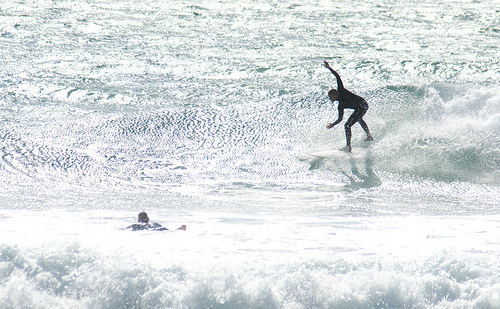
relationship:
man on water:
[312, 61, 374, 154] [1, 2, 490, 210]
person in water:
[126, 206, 188, 233] [1, 2, 490, 210]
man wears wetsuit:
[312, 61, 374, 154] [342, 87, 368, 137]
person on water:
[126, 206, 188, 233] [1, 2, 490, 210]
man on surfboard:
[312, 61, 374, 154] [315, 143, 368, 163]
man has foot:
[312, 61, 374, 154] [343, 144, 352, 153]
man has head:
[312, 61, 374, 154] [329, 85, 338, 105]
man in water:
[312, 61, 374, 154] [1, 2, 490, 210]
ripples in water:
[22, 142, 365, 202] [1, 2, 490, 210]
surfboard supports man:
[315, 143, 368, 163] [312, 61, 374, 154]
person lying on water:
[126, 206, 188, 233] [1, 2, 490, 210]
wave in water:
[380, 85, 498, 201] [1, 2, 490, 210]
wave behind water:
[380, 85, 498, 201] [1, 2, 490, 210]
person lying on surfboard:
[126, 206, 188, 233] [125, 228, 199, 237]